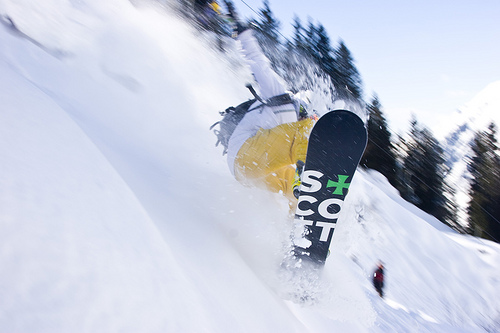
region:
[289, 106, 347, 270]
The board is black.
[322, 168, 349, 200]
The board has a green cross.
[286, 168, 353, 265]
The board has white lettering.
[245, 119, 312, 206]
He is wearing yellow pants.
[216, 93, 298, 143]
He is wearing a white jacket.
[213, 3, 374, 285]
He is doing a trick.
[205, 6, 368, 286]
He is snow boarding.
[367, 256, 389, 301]
He is in the snow.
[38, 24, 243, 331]
The ground is snow covered.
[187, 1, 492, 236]
The trees are green.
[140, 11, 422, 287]
a person on a surfboard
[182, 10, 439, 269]
a person riding a surfboard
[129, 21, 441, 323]
a man riding surfboard on snow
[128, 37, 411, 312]
a person riding snow on mountain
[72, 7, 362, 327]
a person wearing a white jacket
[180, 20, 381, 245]
a person wearing a jacket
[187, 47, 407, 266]
a person wearing pants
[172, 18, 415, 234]
a person wearing yellow pants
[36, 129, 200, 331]
snow covered ground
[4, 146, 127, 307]
white snow covered ground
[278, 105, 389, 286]
black colour snow board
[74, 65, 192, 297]
a place covered with snow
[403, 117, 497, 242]
pine trees with the snow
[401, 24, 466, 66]
a blue colour sky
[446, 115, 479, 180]
a snow covered with the pine tree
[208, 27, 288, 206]
a person with snowsuit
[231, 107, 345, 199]
a person wearing yellow colour pant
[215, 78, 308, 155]
a person holds back bag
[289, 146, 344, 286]
in snowboard letters written in white colour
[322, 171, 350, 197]
some green colour symbol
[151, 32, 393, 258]
a person snowboarding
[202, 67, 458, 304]
a person riding on a snowboard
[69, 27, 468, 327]
a snowboarder on a mountain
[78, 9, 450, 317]
a snowboarder riding on snow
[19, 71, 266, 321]
snow covered mountains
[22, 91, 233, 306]
white snow covered mountain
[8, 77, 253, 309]
mountain covered in snow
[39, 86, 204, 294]
mountain covered in white snow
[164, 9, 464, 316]
a person on a snowboard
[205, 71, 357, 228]
person is on snowboard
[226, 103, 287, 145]
person has white coat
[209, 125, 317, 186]
person has yellow pants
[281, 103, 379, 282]
black and white snowboard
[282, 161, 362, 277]
white letters on snowboard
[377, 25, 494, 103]
sky is blue with few clouds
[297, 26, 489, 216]
green pine trees in background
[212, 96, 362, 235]
snowboarder is spinning while jumping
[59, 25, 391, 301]
snowboarder goes downhill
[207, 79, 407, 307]
snowboarder makes tracks on hill